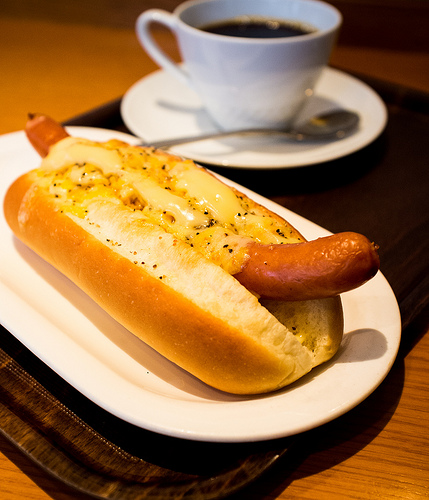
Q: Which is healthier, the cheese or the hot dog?
A: The cheese is healthier than the hot dog.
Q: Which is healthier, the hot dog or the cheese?
A: The cheese is healthier than the hot dog.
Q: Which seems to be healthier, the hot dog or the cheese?
A: The cheese is healthier than the hot dog.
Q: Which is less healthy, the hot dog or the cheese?
A: The hot dog is less healthy than the cheese.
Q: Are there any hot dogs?
A: Yes, there is a hot dog.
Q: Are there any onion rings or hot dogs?
A: Yes, there is a hot dog.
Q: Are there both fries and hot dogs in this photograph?
A: No, there is a hot dog but no fries.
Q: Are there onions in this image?
A: No, there are no onions.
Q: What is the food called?
A: The food is a hot dog.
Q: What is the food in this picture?
A: The food is a hot dog.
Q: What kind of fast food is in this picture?
A: The fast food is a hot dog.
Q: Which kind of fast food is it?
A: The food is a hot dog.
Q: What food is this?
A: This is a hot dog.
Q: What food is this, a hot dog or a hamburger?
A: This is a hot dog.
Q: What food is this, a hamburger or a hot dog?
A: This is a hot dog.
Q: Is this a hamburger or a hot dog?
A: This is a hot dog.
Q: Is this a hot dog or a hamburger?
A: This is a hot dog.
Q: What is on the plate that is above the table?
A: The hot dog is on the plate.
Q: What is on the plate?
A: The hot dog is on the plate.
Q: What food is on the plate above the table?
A: The food is a hot dog.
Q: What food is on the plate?
A: The food is a hot dog.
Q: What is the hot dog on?
A: The hot dog is on the plate.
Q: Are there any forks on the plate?
A: No, there is a hot dog on the plate.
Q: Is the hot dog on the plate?
A: Yes, the hot dog is on the plate.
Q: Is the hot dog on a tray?
A: No, the hot dog is on the plate.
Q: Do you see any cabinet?
A: No, there are no cabinets.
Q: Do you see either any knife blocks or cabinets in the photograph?
A: No, there are no cabinets or knife blocks.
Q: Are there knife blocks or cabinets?
A: No, there are no cabinets or knife blocks.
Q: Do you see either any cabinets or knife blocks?
A: No, there are no cabinets or knife blocks.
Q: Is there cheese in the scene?
A: Yes, there is cheese.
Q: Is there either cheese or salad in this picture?
A: Yes, there is cheese.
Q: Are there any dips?
A: No, there are no dips.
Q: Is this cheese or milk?
A: This is cheese.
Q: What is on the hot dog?
A: The cheese is on the hot dog.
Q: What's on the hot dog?
A: The cheese is on the hot dog.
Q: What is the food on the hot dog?
A: The food is cheese.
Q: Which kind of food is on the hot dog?
A: The food is cheese.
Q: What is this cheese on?
A: The cheese is on the hot dog.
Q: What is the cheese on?
A: The cheese is on the hot dog.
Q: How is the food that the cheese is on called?
A: The food is a hot dog.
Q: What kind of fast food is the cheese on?
A: The cheese is on the hot dog.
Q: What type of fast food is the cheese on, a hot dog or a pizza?
A: The cheese is on a hot dog.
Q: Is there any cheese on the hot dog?
A: Yes, there is cheese on the hot dog.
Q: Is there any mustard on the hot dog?
A: No, there is cheese on the hot dog.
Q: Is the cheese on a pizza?
A: No, the cheese is on a hot dog.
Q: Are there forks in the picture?
A: No, there are no forks.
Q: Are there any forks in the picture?
A: No, there are no forks.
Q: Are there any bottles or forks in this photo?
A: No, there are no forks or bottles.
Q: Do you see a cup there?
A: Yes, there is a cup.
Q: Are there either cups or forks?
A: Yes, there is a cup.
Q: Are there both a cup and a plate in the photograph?
A: Yes, there are both a cup and a plate.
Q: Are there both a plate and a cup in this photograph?
A: Yes, there are both a cup and a plate.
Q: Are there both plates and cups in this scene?
A: Yes, there are both a cup and a plate.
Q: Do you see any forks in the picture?
A: No, there are no forks.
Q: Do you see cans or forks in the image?
A: No, there are no forks or cans.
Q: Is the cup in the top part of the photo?
A: Yes, the cup is in the top of the image.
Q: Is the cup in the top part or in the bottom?
A: The cup is in the top of the image.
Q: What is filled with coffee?
A: The cup is filled with coffee.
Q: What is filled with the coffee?
A: The cup is filled with coffee.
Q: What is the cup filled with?
A: The cup is filled with coffee.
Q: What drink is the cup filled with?
A: The cup is filled with coffee.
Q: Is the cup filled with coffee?
A: Yes, the cup is filled with coffee.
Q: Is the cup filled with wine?
A: No, the cup is filled with coffee.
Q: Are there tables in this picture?
A: Yes, there is a table.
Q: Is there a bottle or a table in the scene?
A: Yes, there is a table.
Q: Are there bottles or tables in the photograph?
A: Yes, there is a table.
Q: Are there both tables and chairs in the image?
A: No, there is a table but no chairs.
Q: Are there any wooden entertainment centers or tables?
A: Yes, there is a wood table.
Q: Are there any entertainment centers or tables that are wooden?
A: Yes, the table is wooden.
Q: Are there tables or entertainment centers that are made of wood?
A: Yes, the table is made of wood.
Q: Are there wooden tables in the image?
A: Yes, there is a wood table.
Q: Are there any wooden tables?
A: Yes, there is a wood table.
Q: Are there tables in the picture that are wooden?
A: Yes, there is a wood table.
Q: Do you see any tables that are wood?
A: Yes, there is a wood table.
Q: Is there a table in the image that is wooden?
A: Yes, there is a table that is wooden.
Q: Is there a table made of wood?
A: Yes, there is a table that is made of wood.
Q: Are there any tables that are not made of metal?
A: Yes, there is a table that is made of wood.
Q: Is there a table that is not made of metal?
A: Yes, there is a table that is made of wood.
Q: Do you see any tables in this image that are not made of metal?
A: Yes, there is a table that is made of wood.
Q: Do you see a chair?
A: No, there are no chairs.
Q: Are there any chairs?
A: No, there are no chairs.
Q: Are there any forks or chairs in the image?
A: No, there are no chairs or forks.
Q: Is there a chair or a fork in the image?
A: No, there are no chairs or forks.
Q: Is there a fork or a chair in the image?
A: No, there are no chairs or forks.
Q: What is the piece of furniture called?
A: The piece of furniture is a table.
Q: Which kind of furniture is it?
A: The piece of furniture is a table.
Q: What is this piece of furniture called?
A: This is a table.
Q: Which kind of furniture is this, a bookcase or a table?
A: This is a table.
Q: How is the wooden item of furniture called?
A: The piece of furniture is a table.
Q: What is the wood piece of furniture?
A: The piece of furniture is a table.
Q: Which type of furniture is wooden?
A: The furniture is a table.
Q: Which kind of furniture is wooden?
A: The furniture is a table.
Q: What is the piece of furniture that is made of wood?
A: The piece of furniture is a table.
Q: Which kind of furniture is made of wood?
A: The furniture is a table.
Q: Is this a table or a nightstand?
A: This is a table.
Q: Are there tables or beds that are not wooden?
A: No, there is a table but it is wooden.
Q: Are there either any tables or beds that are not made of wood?
A: No, there is a table but it is made of wood.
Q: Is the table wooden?
A: Yes, the table is wooden.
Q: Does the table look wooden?
A: Yes, the table is wooden.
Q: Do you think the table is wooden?
A: Yes, the table is wooden.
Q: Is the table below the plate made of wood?
A: Yes, the table is made of wood.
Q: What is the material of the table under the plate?
A: The table is made of wood.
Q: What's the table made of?
A: The table is made of wood.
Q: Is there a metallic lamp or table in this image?
A: No, there is a table but it is wooden.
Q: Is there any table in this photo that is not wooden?
A: No, there is a table but it is wooden.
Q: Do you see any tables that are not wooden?
A: No, there is a table but it is wooden.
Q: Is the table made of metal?
A: No, the table is made of wood.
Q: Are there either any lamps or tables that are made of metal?
A: No, there is a table but it is made of wood.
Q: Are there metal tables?
A: No, there is a table but it is made of wood.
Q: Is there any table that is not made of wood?
A: No, there is a table but it is made of wood.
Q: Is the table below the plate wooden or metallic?
A: The table is wooden.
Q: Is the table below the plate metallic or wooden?
A: The table is wooden.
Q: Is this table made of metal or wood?
A: The table is made of wood.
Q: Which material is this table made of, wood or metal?
A: The table is made of wood.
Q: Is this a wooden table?
A: Yes, this is a wooden table.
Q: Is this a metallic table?
A: No, this is a wooden table.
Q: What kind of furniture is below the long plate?
A: The piece of furniture is a table.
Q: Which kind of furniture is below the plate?
A: The piece of furniture is a table.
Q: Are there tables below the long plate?
A: Yes, there is a table below the plate.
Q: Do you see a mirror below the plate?
A: No, there is a table below the plate.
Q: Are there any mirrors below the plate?
A: No, there is a table below the plate.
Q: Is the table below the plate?
A: Yes, the table is below the plate.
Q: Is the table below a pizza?
A: No, the table is below the plate.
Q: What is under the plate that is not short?
A: The table is under the plate.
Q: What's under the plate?
A: The table is under the plate.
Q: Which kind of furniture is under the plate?
A: The piece of furniture is a table.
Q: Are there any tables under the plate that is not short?
A: Yes, there is a table under the plate.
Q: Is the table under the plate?
A: Yes, the table is under the plate.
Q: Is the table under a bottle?
A: No, the table is under the plate.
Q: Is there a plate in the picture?
A: Yes, there is a plate.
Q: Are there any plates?
A: Yes, there is a plate.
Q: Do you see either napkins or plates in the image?
A: Yes, there is a plate.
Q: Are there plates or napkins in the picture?
A: Yes, there is a plate.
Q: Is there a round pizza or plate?
A: Yes, there is a round plate.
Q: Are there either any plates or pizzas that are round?
A: Yes, the plate is round.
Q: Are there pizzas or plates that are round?
A: Yes, the plate is round.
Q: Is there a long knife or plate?
A: Yes, there is a long plate.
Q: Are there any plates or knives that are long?
A: Yes, the plate is long.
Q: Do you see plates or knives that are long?
A: Yes, the plate is long.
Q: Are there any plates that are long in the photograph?
A: Yes, there is a long plate.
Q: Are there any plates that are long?
A: Yes, there is a plate that is long.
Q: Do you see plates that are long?
A: Yes, there is a plate that is long.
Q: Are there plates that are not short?
A: Yes, there is a long plate.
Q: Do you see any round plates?
A: Yes, there is a round plate.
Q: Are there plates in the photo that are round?
A: Yes, there is a plate that is round.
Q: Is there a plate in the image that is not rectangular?
A: Yes, there is a round plate.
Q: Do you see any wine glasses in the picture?
A: No, there are no wine glasses.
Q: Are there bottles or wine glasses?
A: No, there are no wine glasses or bottles.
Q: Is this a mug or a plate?
A: This is a plate.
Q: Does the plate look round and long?
A: Yes, the plate is round and long.